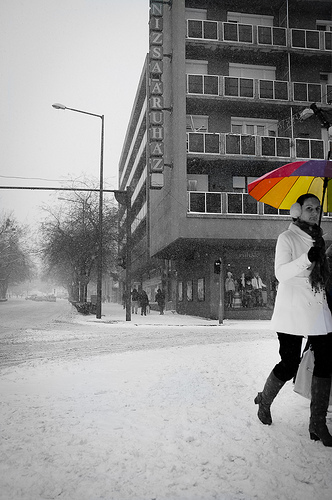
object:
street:
[0, 286, 331, 498]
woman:
[254, 192, 332, 448]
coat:
[268, 220, 332, 339]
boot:
[253, 371, 286, 426]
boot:
[308, 373, 332, 448]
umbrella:
[246, 156, 332, 268]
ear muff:
[289, 201, 302, 220]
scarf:
[293, 216, 332, 294]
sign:
[145, 1, 165, 191]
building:
[115, 1, 330, 327]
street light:
[49, 102, 104, 320]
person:
[154, 287, 166, 316]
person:
[138, 288, 148, 315]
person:
[130, 287, 139, 314]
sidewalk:
[76, 295, 217, 328]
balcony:
[186, 53, 289, 106]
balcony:
[186, 1, 287, 52]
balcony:
[185, 101, 291, 161]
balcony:
[186, 158, 292, 218]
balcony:
[291, 8, 331, 50]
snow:
[2, 284, 332, 500]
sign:
[213, 256, 221, 275]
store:
[175, 243, 282, 321]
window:
[221, 260, 279, 314]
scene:
[0, 3, 331, 500]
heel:
[254, 393, 263, 406]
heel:
[309, 431, 320, 442]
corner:
[154, 237, 211, 316]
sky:
[0, 3, 150, 273]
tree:
[59, 185, 125, 305]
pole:
[218, 251, 225, 325]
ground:
[2, 296, 331, 499]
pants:
[273, 331, 332, 383]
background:
[0, 0, 332, 326]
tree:
[38, 206, 81, 304]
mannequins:
[225, 265, 270, 312]